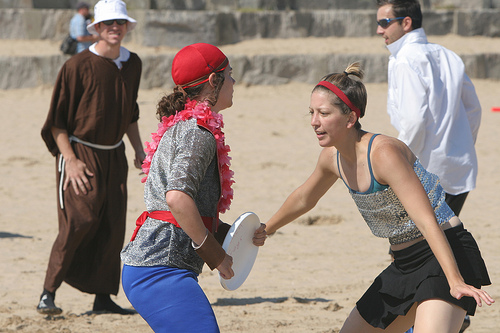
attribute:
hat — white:
[82, 0, 136, 38]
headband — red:
[312, 77, 364, 119]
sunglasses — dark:
[373, 14, 401, 28]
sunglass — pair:
[85, 12, 147, 32]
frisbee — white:
[216, 208, 263, 293]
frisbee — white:
[228, 181, 263, 293]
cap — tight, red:
[171, 29, 233, 86]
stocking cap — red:
[168, 46, 230, 87]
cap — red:
[169, 40, 232, 87]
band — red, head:
[316, 80, 365, 117]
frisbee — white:
[220, 212, 259, 291]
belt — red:
[130, 210, 221, 241]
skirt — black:
[357, 225, 497, 317]